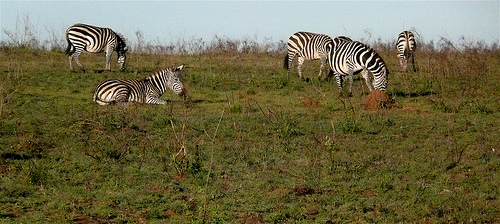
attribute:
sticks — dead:
[122, 26, 294, 58]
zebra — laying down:
[67, 66, 199, 134]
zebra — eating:
[52, 11, 139, 84]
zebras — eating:
[256, 25, 441, 134]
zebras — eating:
[370, 33, 438, 95]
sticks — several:
[82, 110, 250, 219]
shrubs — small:
[68, 103, 381, 221]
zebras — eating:
[56, 30, 466, 137]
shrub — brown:
[363, 80, 423, 129]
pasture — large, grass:
[44, 90, 493, 220]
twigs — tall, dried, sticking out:
[150, 110, 240, 185]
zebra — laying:
[75, 54, 223, 127]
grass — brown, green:
[17, 43, 422, 215]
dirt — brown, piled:
[353, 90, 413, 133]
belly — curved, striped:
[29, 21, 129, 72]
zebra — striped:
[284, 24, 413, 127]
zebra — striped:
[248, 17, 382, 117]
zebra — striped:
[262, 13, 444, 76]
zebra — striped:
[251, 21, 440, 113]